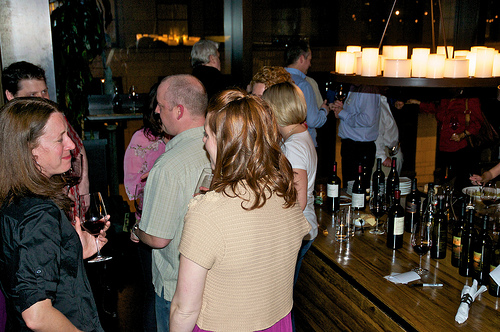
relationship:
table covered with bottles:
[289, 180, 499, 330] [348, 162, 367, 209]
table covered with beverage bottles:
[289, 180, 499, 330] [321, 159, 342, 217]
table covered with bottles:
[289, 180, 499, 330] [371, 157, 384, 204]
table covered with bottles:
[289, 180, 499, 330] [384, 153, 401, 206]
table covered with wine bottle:
[289, 180, 499, 330] [385, 187, 406, 250]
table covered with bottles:
[289, 180, 499, 330] [403, 176, 419, 231]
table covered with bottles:
[289, 180, 499, 330] [472, 214, 494, 284]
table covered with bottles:
[289, 180, 499, 330] [458, 207, 476, 272]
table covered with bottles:
[289, 180, 499, 330] [429, 195, 446, 263]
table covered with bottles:
[289, 180, 499, 330] [448, 200, 471, 266]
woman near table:
[166, 87, 311, 329] [291, 194, 496, 329]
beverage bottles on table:
[327, 140, 476, 270] [289, 180, 499, 330]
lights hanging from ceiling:
[329, 39, 498, 91] [17, 0, 498, 9]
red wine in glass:
[80, 218, 107, 238] [77, 191, 115, 265]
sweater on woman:
[169, 162, 305, 329] [171, 97, 331, 329]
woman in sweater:
[166, 87, 311, 329] [175, 173, 315, 332]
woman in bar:
[166, 87, 311, 329] [0, 1, 495, 329]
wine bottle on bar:
[384, 163, 411, 253] [248, 166, 495, 330]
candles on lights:
[345, 39, 446, 84] [328, 43, 500, 89]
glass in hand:
[77, 191, 114, 262] [73, 206, 120, 260]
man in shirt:
[137, 71, 216, 330] [131, 122, 214, 307]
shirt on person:
[422, 99, 464, 140] [411, 55, 481, 175]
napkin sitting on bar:
[380, 266, 429, 287] [301, 245, 393, 329]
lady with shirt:
[0, 93, 107, 330] [3, 177, 104, 329]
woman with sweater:
[172, 87, 312, 332] [175, 173, 315, 332]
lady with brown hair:
[0, 93, 107, 330] [0, 94, 80, 202]